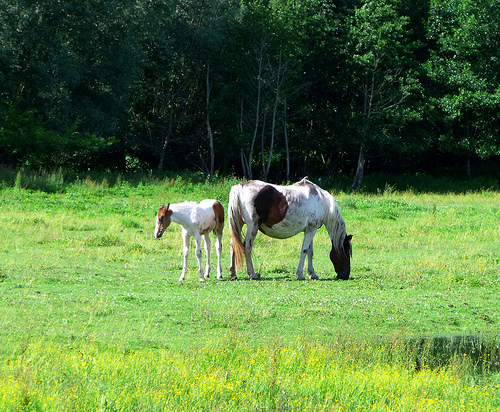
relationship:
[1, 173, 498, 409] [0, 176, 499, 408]
field of grass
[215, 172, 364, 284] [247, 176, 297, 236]
horse with spot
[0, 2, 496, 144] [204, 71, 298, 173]
leaves on branches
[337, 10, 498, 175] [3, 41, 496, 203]
tree in woods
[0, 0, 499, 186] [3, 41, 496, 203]
tree in woods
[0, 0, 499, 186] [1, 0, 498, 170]
tree in woods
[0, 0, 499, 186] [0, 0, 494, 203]
tree in woods